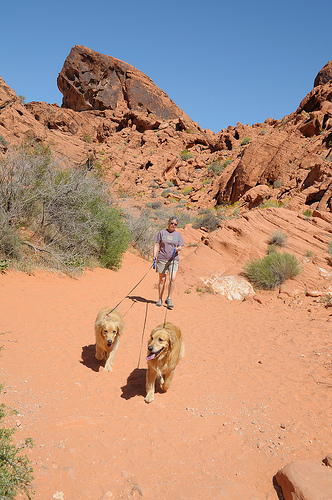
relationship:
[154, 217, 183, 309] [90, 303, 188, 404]
person walking dogs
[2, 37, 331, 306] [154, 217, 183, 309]
rocks behind person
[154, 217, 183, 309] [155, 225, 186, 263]
person wearing shirt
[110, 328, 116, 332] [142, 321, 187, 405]
eye of dog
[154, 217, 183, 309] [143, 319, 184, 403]
person walking dog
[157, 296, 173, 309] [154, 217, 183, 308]
shoe on person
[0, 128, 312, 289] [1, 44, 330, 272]
bushes in mountains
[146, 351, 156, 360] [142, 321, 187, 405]
tongue of dog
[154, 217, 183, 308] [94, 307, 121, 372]
person walking dog